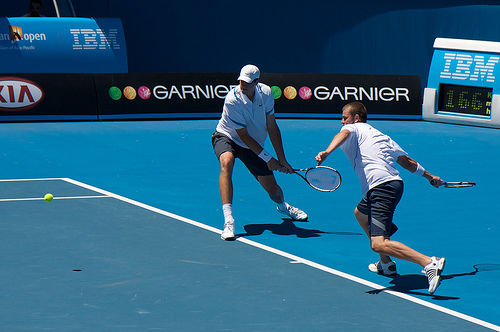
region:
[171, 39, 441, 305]
players are trying to hit the ball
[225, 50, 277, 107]
the cap is white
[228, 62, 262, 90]
the cap is white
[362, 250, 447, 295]
Man wearing shoes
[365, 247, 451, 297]
Man is wearing shoes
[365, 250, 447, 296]
Man wearing black and white shoes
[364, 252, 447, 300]
Man is wearing black and white shoes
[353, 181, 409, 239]
Man wearing shorts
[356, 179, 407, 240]
Man wearing blue and gray shorts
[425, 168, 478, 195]
Man holding a tennis racket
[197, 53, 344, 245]
The man is holding a tennis racket.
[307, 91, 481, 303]
The man is holding a tennis racket.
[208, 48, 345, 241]
The man is wearing a cap.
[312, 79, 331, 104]
The letter is white.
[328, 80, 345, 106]
The letter is white.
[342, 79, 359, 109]
The letter is white.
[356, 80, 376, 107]
The letter is white.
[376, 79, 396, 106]
The letter is white.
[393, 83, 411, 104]
The letter is white.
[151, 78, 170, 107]
The letter is white.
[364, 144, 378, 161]
man wearing white shirt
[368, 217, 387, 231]
purple strip on shorts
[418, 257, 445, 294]
man wearing white sneakers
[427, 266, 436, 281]
black stripes on sneakers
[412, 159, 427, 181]
white band on arm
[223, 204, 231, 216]
man wearing white socks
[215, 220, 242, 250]
man wearing white sneakers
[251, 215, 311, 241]
a shadow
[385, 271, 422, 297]
a shadow on the court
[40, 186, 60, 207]
a tennis ball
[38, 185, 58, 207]
the tennis ball is green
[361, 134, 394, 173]
a white shirt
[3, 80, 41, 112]
a logo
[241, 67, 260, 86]
man is wearing a white hat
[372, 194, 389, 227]
man is wearing blue shors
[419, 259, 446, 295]
white shoe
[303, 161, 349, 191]
a tennis racket